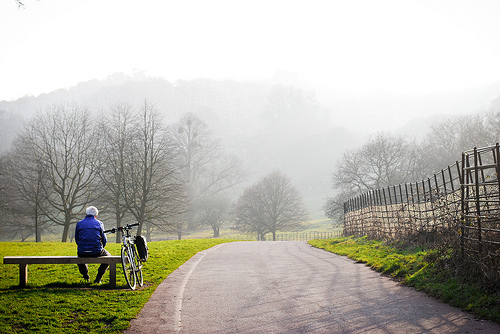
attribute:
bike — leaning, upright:
[102, 218, 150, 292]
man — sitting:
[68, 202, 112, 283]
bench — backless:
[2, 254, 135, 288]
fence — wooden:
[244, 142, 498, 283]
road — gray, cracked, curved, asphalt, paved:
[138, 230, 494, 332]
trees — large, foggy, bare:
[2, 108, 499, 240]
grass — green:
[0, 240, 233, 333]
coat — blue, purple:
[68, 217, 111, 252]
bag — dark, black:
[131, 233, 154, 261]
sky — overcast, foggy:
[0, 1, 499, 141]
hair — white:
[85, 205, 100, 218]